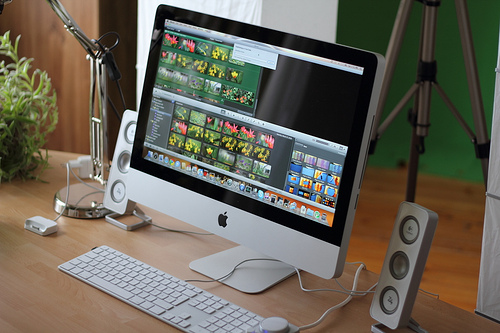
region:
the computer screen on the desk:
[129, 4, 386, 280]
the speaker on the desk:
[366, 196, 443, 332]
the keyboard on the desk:
[58, 242, 259, 332]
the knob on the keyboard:
[257, 309, 293, 331]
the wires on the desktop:
[248, 258, 368, 303]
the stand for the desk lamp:
[51, 2, 114, 169]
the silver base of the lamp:
[54, 179, 107, 222]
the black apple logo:
[211, 210, 233, 230]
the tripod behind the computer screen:
[387, 5, 487, 199]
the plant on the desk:
[0, 27, 65, 175]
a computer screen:
[136, 34, 368, 286]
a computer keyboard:
[62, 248, 232, 322]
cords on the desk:
[261, 254, 351, 325]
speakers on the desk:
[361, 203, 439, 328]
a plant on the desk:
[0, 43, 56, 171]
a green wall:
[387, 44, 480, 158]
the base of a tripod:
[385, 35, 472, 164]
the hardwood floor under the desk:
[442, 177, 473, 247]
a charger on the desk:
[23, 205, 70, 230]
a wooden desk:
[7, 152, 414, 328]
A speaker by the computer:
[368, 200, 435, 327]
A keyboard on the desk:
[57, 246, 297, 332]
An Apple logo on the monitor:
[216, 209, 228, 227]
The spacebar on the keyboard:
[88, 275, 133, 298]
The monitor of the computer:
[125, 3, 383, 280]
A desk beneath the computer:
[1, 149, 499, 331]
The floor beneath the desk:
[345, 159, 482, 314]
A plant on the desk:
[1, 31, 59, 183]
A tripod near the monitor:
[370, 1, 489, 201]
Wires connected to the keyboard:
[181, 262, 436, 332]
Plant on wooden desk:
[0, 31, 60, 192]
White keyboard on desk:
[56, 241, 298, 331]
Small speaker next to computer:
[102, 106, 152, 233]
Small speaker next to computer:
[366, 200, 438, 330]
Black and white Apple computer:
[122, 1, 388, 296]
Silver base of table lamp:
[46, 0, 118, 221]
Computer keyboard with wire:
[58, 241, 313, 332]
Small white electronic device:
[20, 212, 58, 236]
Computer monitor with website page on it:
[124, 3, 389, 294]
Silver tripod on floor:
[363, 0, 490, 208]